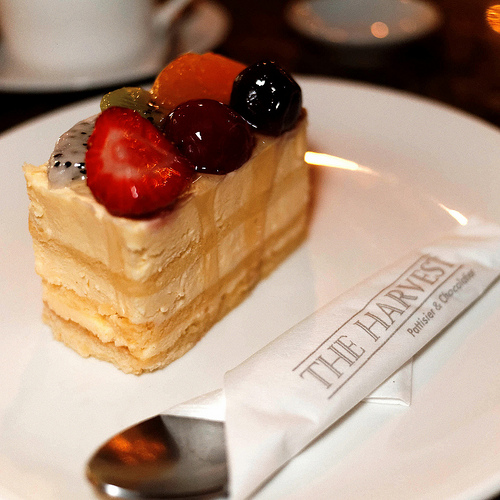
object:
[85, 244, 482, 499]
spoon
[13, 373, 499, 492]
dessert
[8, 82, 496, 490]
plate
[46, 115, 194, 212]
strawberries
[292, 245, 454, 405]
harvest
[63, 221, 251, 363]
ice cream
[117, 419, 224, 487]
bowl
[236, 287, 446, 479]
napkin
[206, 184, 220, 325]
fruit juices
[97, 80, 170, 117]
kiwi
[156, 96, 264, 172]
cherry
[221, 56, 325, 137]
blueberry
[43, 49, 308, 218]
mixed fruit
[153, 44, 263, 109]
orange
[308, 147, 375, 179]
light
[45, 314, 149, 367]
layers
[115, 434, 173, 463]
reflection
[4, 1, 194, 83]
coffee mug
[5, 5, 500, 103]
background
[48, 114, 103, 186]
raspberry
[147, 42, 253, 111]
dragonfruit